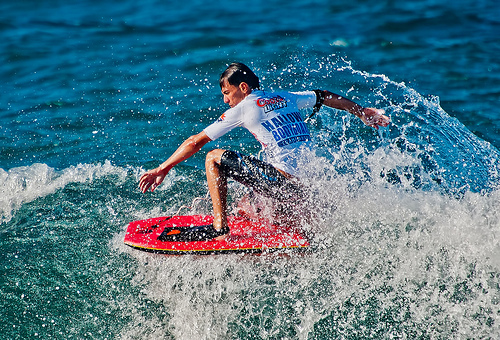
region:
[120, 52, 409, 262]
A man surfing in the sea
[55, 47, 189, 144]
Waters of the sea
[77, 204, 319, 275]
A red surfboard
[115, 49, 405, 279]
A man surfing alone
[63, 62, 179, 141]
Blue color of the sea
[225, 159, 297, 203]
Black shorts in the photo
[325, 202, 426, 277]
Water splashed in the photo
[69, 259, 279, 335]
Waves of the sea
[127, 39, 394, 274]
A man in the photo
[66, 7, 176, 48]
Turbulent sea waters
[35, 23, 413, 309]
a man is surfing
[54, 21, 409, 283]
the surfer has a wet shirt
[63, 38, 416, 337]
the surfer has dark hair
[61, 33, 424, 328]
the surfer is male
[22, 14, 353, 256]
the surfer is sponsored by coors light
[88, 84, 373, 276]
surfboard is red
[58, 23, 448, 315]
surfer has shorts on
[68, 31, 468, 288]
the surfer crests the wave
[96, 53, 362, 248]
the text is hallow bodyguard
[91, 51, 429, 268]
the hands are spread for balance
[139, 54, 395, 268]
this is a person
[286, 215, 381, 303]
a wave in the water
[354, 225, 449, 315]
a wave in the water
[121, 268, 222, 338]
a wave in the water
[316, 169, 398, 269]
a wave in the water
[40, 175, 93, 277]
a wave in the water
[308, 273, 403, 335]
a wave in the water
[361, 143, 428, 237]
a wave in the water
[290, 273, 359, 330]
a wave in the water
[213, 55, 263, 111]
head of a person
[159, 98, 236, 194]
arm of a person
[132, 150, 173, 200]
hand of a person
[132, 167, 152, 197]
finger of a person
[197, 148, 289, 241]
leg of a person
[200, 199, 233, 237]
feet of a person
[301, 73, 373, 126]
arm of a person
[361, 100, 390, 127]
hand of a person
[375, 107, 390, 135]
finger of a person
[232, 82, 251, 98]
ear of a person